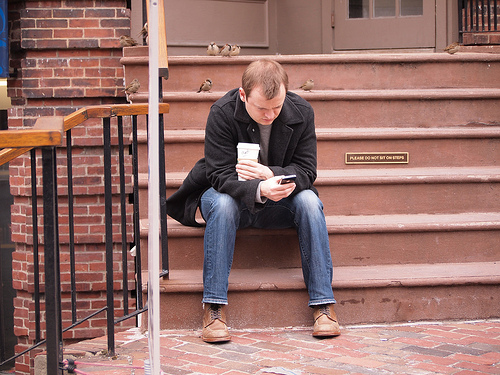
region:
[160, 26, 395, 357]
A man is sitting on the stairs.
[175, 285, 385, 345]
A man is wearing brown shoes.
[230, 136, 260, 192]
The man is holding a cup of coffee.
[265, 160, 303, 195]
A man is holding a cell phone.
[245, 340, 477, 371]
Bricks are on the ground.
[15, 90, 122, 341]
Red bricks are on the building.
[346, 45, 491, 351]
Six steps are on this set of stairs.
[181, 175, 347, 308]
The man is wearing jeans.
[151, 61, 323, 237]
The man is wearnig a black jacket.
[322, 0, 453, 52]
A door at the top of the stairs.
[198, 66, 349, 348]
man sitting on steps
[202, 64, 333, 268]
man drinking a hot beverage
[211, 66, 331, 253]
man looking at his smartphone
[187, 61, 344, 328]
man wearing blue jeans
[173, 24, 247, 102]
birds standing on steps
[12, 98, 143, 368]
metal and wood railing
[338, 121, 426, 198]
small sign on outdoor steps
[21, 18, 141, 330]
red brick building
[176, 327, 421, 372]
red brick walkway under man's feet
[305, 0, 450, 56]
wood and glass door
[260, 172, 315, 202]
hand hold black cellphone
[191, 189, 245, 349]
leg with blue jeans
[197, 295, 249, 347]
brown men's boot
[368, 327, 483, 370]
red floor diagonal laid brick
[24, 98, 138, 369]
black iron gate with wood railing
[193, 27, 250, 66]
birds sitting on steps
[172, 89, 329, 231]
black men's jacket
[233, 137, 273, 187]
hand holding a coffee cup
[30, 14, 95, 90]
brick stained wall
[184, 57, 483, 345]
hand sitting on front door steps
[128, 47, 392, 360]
A man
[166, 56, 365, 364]
A man sitting down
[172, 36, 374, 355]
A man sitting on steps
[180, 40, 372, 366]
A man holding a cell phone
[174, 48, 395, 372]
A man holding a paper cup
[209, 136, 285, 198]
A cup with a lid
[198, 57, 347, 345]
A man wearing jeans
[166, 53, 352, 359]
A man wearing brown shoes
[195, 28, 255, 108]
birds sitting on steps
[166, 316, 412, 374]
feet on a brick pavement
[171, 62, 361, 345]
man wearing coat and jeans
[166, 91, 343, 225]
black fall coat on man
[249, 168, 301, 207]
black apple cell phone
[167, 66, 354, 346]
man holding black phone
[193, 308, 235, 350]
left shoe of man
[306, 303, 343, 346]
right shoe of man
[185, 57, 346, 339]
man wearing brown shoes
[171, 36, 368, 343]
man holding coffee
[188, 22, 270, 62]
birds sitting on top step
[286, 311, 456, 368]
red brick steps by man